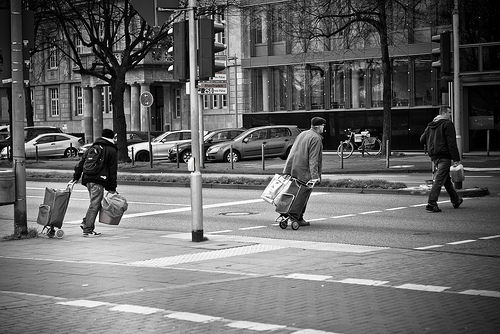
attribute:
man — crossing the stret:
[75, 93, 138, 282]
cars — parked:
[43, 133, 280, 163]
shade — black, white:
[31, 14, 424, 317]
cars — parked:
[105, 135, 299, 147]